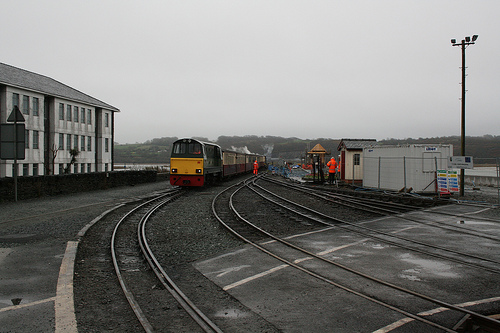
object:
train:
[168, 137, 268, 189]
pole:
[459, 41, 467, 195]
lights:
[448, 37, 459, 44]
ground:
[21, 192, 79, 234]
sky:
[105, 2, 445, 103]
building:
[0, 64, 119, 179]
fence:
[0, 174, 55, 197]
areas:
[12, 200, 60, 245]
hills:
[116, 129, 499, 152]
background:
[3, 8, 497, 151]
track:
[107, 185, 203, 332]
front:
[169, 138, 205, 187]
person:
[326, 154, 340, 183]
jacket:
[252, 158, 259, 174]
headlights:
[169, 167, 179, 174]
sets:
[118, 187, 188, 221]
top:
[324, 156, 340, 168]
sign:
[434, 169, 462, 194]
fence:
[361, 157, 416, 187]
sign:
[7, 104, 26, 122]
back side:
[1, 122, 25, 160]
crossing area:
[188, 203, 500, 330]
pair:
[107, 203, 158, 265]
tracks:
[107, 184, 218, 332]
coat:
[326, 160, 337, 175]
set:
[451, 34, 481, 49]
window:
[55, 132, 67, 152]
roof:
[0, 62, 117, 113]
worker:
[252, 156, 260, 178]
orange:
[251, 161, 261, 174]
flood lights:
[448, 35, 478, 194]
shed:
[339, 142, 381, 182]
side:
[288, 116, 497, 208]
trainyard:
[57, 175, 498, 333]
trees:
[275, 137, 292, 153]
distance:
[4, 129, 499, 158]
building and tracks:
[0, 60, 500, 329]